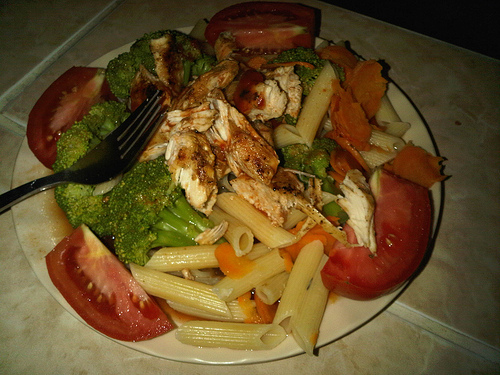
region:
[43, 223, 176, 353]
An eighth of a fresh tomato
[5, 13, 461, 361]
Penne with chicken, broccoli, and tomatos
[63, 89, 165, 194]
Head of a stainless steel fork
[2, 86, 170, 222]
Stainless steel fork resting on cooked broccoli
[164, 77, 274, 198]
Pieces of oven roased chicken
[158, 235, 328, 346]
A grouping of cooked penne noodles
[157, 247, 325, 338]
A grouping of cooked ziti noodles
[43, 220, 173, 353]
A glistening tomato wedge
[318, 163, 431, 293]
Piece of roasted chick on top of a tomato wedge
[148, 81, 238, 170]
Part of a fork and some shredded roasted chicken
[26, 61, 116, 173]
quarter of a tomato on a plate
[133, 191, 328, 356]
penne pasta on a plate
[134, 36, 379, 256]
bits of chicken on a plate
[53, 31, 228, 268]
broccoli heads on a plate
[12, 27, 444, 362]
a white plate on a tile counter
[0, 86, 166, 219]
a fork propped on a plate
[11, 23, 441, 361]
a plate with chicken, pasta and veggies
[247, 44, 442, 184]
bits of tuna on penne pasta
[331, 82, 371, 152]
a bit of tuna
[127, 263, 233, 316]
a penne pasta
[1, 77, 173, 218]
Silver piece of silverware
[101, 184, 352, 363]
Pieces of penne pasta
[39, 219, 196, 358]
quarter slice of tomato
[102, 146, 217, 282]
Piece of broccoli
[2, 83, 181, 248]
Silver fork for eating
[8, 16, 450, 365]
White plate with food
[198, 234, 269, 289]
Piece of orange sauce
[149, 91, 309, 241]
Pieces of brown chicken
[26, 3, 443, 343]
Four slices of tomato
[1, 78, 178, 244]
Four prongs on silver fork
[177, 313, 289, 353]
A pasta noodle on a plate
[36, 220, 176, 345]
A sliced tomato on a plate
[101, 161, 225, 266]
A green piece on broccoli on a plate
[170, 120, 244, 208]
Grilled chicken on a plate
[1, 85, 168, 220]
A metal fork in a meal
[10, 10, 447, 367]
A large plate of food on the table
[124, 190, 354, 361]
Numerous pasta noodles in a meal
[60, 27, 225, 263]
Numerous piece of broccoli in a meal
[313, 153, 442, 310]
A chopped piece of tomato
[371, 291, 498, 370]
Caulk line between tiles